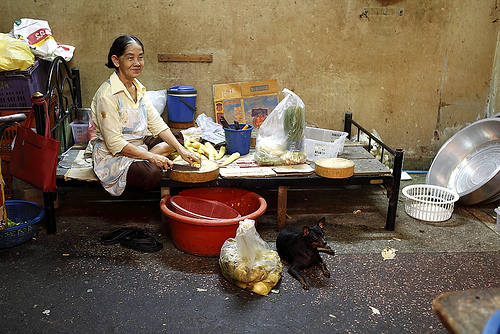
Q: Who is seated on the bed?
A: An old smiling lady.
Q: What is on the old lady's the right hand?
A: A knife.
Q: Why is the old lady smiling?
A: Because she is posing for the picture.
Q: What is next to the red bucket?
A: A black small dog.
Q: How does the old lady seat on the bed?
A: With her legs crossed.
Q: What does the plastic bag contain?
A: Vegetables.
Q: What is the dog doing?
A: Laying on the floor.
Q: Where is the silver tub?
A: Right side.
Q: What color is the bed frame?
A: Black.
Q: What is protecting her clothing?
A: Apron.